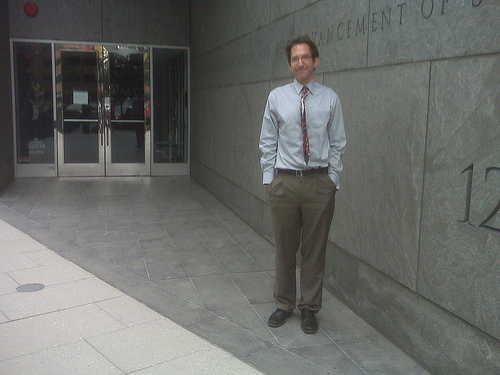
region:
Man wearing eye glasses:
[283, 37, 323, 84]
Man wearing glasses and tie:
[260, 37, 349, 194]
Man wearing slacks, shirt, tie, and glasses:
[258, 34, 343, 338]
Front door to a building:
[7, 33, 192, 181]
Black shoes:
[264, 305, 321, 336]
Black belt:
[274, 163, 331, 178]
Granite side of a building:
[357, 63, 449, 350]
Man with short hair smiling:
[282, 35, 319, 85]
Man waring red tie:
[260, 33, 347, 193]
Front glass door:
[53, 42, 152, 177]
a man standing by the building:
[240, 32, 360, 337]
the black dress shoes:
[266, 306, 321, 335]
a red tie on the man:
[297, 86, 314, 168]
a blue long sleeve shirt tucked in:
[259, 76, 344, 191]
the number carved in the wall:
[452, 149, 499, 241]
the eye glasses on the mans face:
[289, 50, 316, 64]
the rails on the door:
[96, 106, 111, 141]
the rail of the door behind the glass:
[60, 111, 99, 126]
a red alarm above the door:
[20, 0, 40, 23]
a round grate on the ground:
[14, 273, 47, 297]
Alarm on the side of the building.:
[18, 2, 48, 17]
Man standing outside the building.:
[266, 32, 341, 337]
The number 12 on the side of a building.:
[456, 154, 497, 236]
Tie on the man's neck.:
[295, 80, 316, 165]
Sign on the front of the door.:
[71, 84, 91, 106]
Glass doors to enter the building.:
[55, 37, 152, 184]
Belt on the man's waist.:
[278, 159, 330, 184]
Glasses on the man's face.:
[289, 50, 315, 65]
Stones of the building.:
[204, 47, 261, 170]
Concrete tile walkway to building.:
[44, 182, 167, 372]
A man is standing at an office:
[37, 6, 477, 352]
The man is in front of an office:
[37, 15, 478, 352]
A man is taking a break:
[12, 16, 484, 357]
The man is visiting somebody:
[0, 10, 497, 348]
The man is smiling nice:
[30, 20, 447, 360]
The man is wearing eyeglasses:
[40, 16, 470, 346]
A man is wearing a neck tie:
[35, 20, 482, 360]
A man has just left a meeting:
[21, 7, 487, 360]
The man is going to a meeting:
[36, 20, 476, 368]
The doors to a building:
[55, 41, 147, 177]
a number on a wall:
[461, 158, 499, 239]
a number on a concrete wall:
[454, 161, 499, 236]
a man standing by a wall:
[257, 36, 352, 332]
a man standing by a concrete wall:
[261, 33, 343, 334]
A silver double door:
[10, 38, 195, 178]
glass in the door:
[65, 53, 145, 167]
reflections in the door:
[131, 84, 152, 151]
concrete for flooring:
[32, 248, 147, 359]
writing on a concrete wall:
[307, 10, 488, 47]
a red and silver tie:
[299, 90, 311, 166]